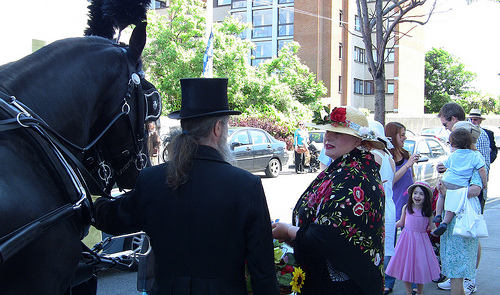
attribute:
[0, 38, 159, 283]
black horse — large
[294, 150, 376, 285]
jacket — black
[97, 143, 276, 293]
jacket — black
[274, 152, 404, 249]
shawl — red , black 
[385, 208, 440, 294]
dress — pink 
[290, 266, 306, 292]
sunflower — yellow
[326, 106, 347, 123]
flower — red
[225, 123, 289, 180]
car — black, parked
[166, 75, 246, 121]
hat — black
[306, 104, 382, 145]
flower — red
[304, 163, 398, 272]
shawl — floral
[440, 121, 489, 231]
child — young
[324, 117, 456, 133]
cover — green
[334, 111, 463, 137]
cover — green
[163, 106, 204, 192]
hair — long